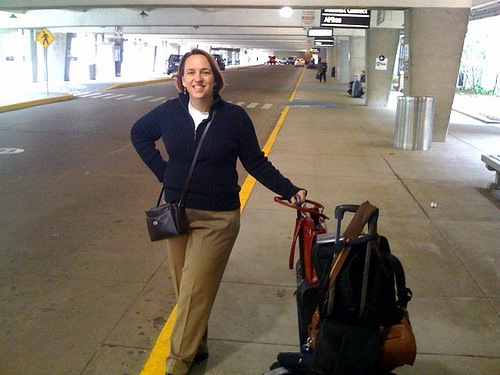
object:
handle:
[271, 196, 326, 223]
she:
[130, 49, 306, 375]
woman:
[126, 47, 315, 370]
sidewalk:
[189, 57, 483, 372]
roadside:
[172, 60, 480, 370]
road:
[2, 63, 314, 370]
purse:
[143, 201, 187, 243]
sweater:
[129, 95, 306, 212]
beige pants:
[160, 208, 241, 375]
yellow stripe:
[293, 62, 307, 106]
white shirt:
[178, 104, 214, 137]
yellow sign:
[32, 30, 55, 49]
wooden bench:
[475, 144, 498, 173]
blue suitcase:
[346, 79, 367, 99]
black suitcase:
[269, 199, 416, 374]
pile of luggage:
[290, 202, 442, 366]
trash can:
[392, 89, 446, 156]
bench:
[482, 149, 500, 193]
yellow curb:
[271, 105, 290, 138]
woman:
[101, 44, 283, 373]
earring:
[181, 85, 189, 90]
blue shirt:
[127, 96, 294, 211]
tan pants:
[146, 196, 237, 370]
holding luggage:
[129, 47, 417, 373]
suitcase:
[297, 202, 418, 365]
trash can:
[380, 79, 449, 166]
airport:
[0, 0, 500, 375]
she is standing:
[129, 48, 305, 374]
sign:
[317, 8, 371, 29]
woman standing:
[126, 51, 303, 364]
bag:
[380, 321, 420, 361]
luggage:
[271, 197, 416, 374]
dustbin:
[393, 95, 435, 151]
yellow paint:
[264, 105, 282, 167]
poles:
[403, 6, 472, 140]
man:
[315, 57, 331, 82]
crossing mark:
[40, 84, 281, 108]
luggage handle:
[333, 202, 381, 238]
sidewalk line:
[0, 94, 82, 112]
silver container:
[392, 95, 436, 151]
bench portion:
[477, 146, 500, 169]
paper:
[426, 201, 442, 213]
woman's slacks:
[149, 196, 260, 374]